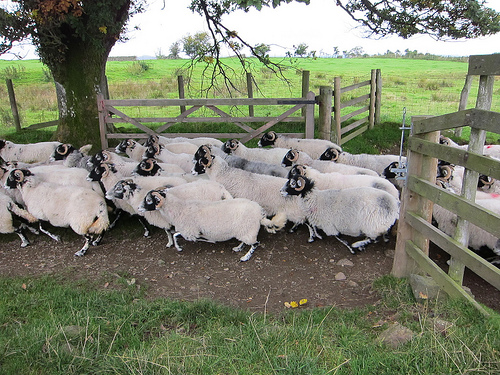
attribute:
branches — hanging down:
[192, 1, 289, 110]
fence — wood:
[384, 53, 498, 329]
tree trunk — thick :
[23, 2, 128, 140]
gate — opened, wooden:
[321, 72, 398, 143]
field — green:
[390, 58, 447, 98]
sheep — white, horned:
[6, 162, 111, 254]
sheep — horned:
[280, 164, 398, 254]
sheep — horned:
[189, 150, 294, 228]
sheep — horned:
[106, 176, 236, 249]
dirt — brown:
[244, 258, 303, 286]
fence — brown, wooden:
[96, 67, 382, 156]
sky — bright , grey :
[134, 2, 496, 51]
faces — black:
[279, 145, 309, 200]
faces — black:
[144, 131, 164, 176]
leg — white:
[351, 237, 377, 249]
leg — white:
[239, 242, 256, 262]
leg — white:
[137, 212, 154, 237]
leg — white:
[75, 230, 88, 259]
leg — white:
[9, 225, 26, 247]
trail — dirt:
[0, 223, 402, 310]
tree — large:
[1, 0, 498, 158]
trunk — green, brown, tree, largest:
[39, 9, 110, 147]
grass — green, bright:
[2, 59, 496, 153]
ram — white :
[1, 170, 108, 255]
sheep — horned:
[137, 190, 262, 258]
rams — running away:
[0, 131, 499, 253]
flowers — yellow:
[279, 296, 311, 312]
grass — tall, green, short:
[5, 278, 495, 372]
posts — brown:
[83, 71, 367, 137]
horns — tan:
[134, 187, 174, 213]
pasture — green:
[7, 58, 483, 116]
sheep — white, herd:
[0, 122, 470, 248]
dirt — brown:
[3, 227, 483, 307]